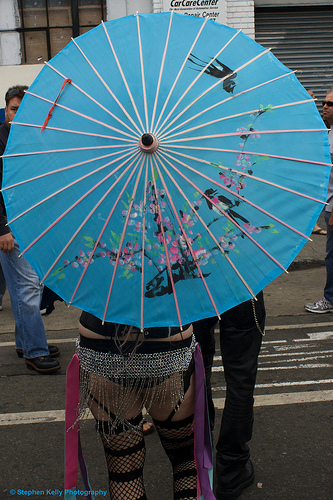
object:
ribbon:
[62, 352, 85, 498]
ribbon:
[188, 342, 218, 498]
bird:
[187, 52, 237, 94]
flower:
[73, 170, 245, 274]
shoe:
[303, 295, 332, 314]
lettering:
[10, 489, 109, 500]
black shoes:
[215, 459, 256, 498]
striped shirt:
[0, 10, 330, 312]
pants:
[216, 284, 266, 460]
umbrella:
[0, 11, 333, 333]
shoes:
[14, 342, 62, 375]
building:
[1, 1, 332, 123]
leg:
[85, 374, 146, 499]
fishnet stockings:
[99, 416, 146, 499]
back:
[145, 355, 199, 499]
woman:
[64, 309, 225, 496]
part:
[164, 264, 234, 299]